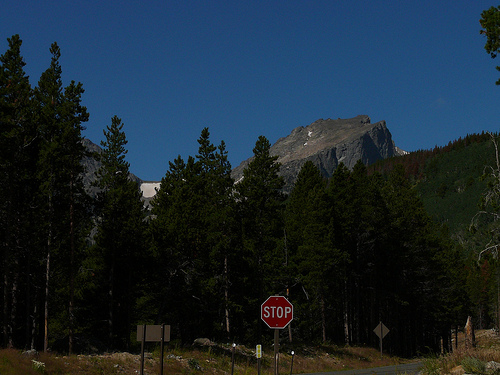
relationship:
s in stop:
[261, 304, 271, 322] [261, 298, 294, 318]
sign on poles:
[259, 295, 294, 328] [134, 326, 175, 371]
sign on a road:
[258, 294, 291, 374] [283, 360, 434, 373]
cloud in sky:
[0, 0, 499, 183] [81, 30, 433, 118]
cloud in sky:
[216, 45, 316, 99] [0, 0, 499, 183]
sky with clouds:
[111, 70, 358, 143] [141, 31, 296, 93]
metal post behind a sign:
[138, 321, 149, 372] [134, 321, 172, 346]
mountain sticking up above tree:
[261, 117, 407, 179] [376, 162, 400, 329]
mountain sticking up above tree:
[261, 117, 407, 179] [290, 165, 337, 310]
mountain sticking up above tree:
[261, 117, 407, 179] [241, 148, 288, 291]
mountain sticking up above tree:
[261, 117, 407, 179] [176, 152, 217, 314]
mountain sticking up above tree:
[261, 117, 407, 179] [91, 127, 158, 306]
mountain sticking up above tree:
[261, 117, 407, 179] [26, 39, 106, 336]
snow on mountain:
[141, 185, 161, 201] [73, 107, 399, 186]